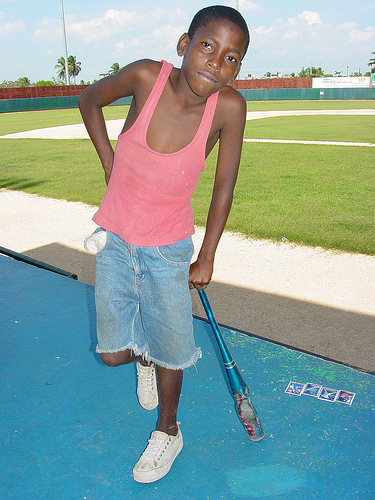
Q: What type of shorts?
A: Jean.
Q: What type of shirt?
A: A tank top.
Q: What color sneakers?
A: White.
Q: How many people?
A: One.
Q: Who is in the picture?
A: A boy.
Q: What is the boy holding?
A: A bat.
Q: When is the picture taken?
A: Daytime.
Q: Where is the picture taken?
A: At a baseball field.